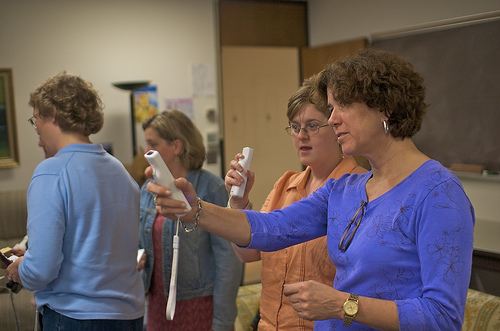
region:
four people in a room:
[3, 1, 495, 330]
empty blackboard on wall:
[371, 9, 498, 178]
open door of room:
[223, 38, 370, 210]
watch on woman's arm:
[284, 281, 398, 328]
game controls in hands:
[144, 145, 256, 217]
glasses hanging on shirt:
[245, 159, 475, 329]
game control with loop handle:
[143, 149, 189, 319]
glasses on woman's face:
[286, 82, 335, 167]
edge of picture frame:
[0, 68, 22, 170]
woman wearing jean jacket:
[139, 108, 243, 329]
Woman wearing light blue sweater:
[3, 71, 148, 330]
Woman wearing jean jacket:
[136, 110, 245, 330]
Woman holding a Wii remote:
[216, 74, 373, 330]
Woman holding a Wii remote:
[140, 47, 476, 329]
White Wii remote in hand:
[142, 145, 199, 223]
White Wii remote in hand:
[223, 146, 257, 205]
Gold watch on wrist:
[341, 292, 358, 327]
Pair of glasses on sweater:
[338, 199, 368, 254]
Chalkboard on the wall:
[370, 10, 498, 184]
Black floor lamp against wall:
[112, 78, 149, 162]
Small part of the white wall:
[102, 25, 134, 44]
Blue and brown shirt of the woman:
[388, 225, 428, 253]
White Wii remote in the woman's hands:
[144, 148, 173, 193]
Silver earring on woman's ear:
[379, 120, 391, 134]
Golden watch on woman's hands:
[343, 293, 360, 325]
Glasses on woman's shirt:
[336, 201, 368, 253]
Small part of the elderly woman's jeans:
[46, 316, 65, 329]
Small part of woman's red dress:
[183, 307, 203, 329]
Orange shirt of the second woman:
[264, 256, 286, 276]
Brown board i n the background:
[461, 35, 486, 55]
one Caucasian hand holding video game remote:
[143, 144, 199, 219]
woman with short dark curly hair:
[318, 47, 426, 160]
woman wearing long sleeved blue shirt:
[250, 48, 475, 330]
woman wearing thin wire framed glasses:
[278, 74, 332, 170]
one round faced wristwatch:
[338, 288, 362, 325]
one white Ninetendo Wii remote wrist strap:
[162, 225, 181, 322]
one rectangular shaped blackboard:
[380, 23, 499, 185]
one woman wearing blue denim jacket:
[131, 108, 239, 328]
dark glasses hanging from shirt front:
[336, 197, 372, 257]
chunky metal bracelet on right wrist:
[179, 195, 204, 237]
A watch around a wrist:
[332, 285, 367, 327]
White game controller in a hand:
[135, 140, 205, 325]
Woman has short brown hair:
[312, 40, 432, 160]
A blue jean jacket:
[130, 161, 245, 326]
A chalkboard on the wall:
[360, 5, 496, 186]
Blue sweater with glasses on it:
[230, 151, 475, 326]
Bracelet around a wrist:
[175, 185, 205, 235]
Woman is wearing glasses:
[275, 66, 342, 171]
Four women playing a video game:
[0, 37, 477, 327]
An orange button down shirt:
[250, 150, 371, 327]